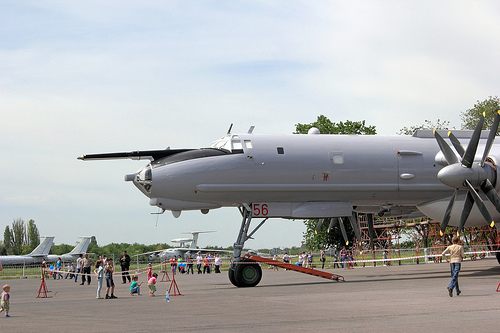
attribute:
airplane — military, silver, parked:
[77, 121, 499, 289]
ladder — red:
[244, 251, 354, 287]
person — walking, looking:
[439, 228, 471, 298]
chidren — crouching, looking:
[123, 273, 159, 293]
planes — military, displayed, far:
[2, 224, 216, 268]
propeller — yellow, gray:
[434, 121, 499, 228]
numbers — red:
[248, 199, 272, 220]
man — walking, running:
[74, 255, 84, 282]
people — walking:
[46, 241, 225, 272]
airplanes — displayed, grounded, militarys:
[6, 111, 499, 281]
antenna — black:
[354, 114, 378, 134]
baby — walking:
[0, 281, 13, 320]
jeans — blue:
[449, 264, 465, 295]